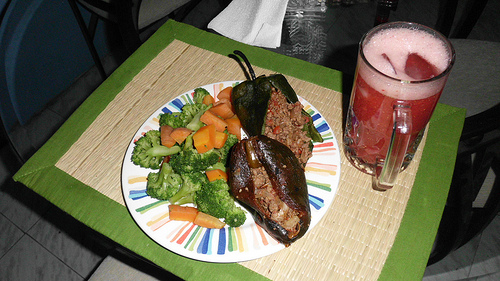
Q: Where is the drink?
A: On the corner.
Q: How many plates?
A: 1.